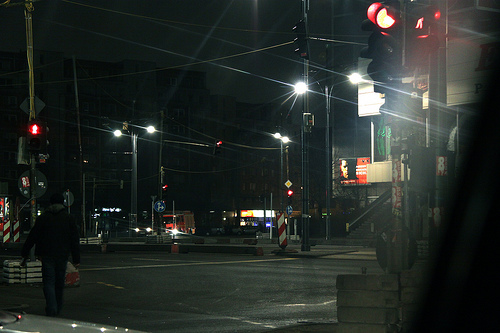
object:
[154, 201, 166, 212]
sign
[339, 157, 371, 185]
billboard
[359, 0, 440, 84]
light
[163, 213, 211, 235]
truck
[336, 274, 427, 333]
brick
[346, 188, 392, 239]
staircase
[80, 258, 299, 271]
lines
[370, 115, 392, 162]
windows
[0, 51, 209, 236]
buildings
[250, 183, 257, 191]
windows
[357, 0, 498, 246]
buildings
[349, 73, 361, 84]
light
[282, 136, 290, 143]
light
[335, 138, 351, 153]
wall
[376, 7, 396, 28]
redlight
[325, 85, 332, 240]
pole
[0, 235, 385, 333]
road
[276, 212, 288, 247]
flags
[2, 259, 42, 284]
cement barriers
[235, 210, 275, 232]
store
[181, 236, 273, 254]
corner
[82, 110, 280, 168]
lines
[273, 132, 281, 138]
lamp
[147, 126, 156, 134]
lamp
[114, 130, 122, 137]
lamp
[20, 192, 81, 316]
man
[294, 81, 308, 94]
light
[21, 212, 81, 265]
jacket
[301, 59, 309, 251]
pole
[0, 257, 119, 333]
corner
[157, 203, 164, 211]
arrows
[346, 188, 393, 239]
balustrade